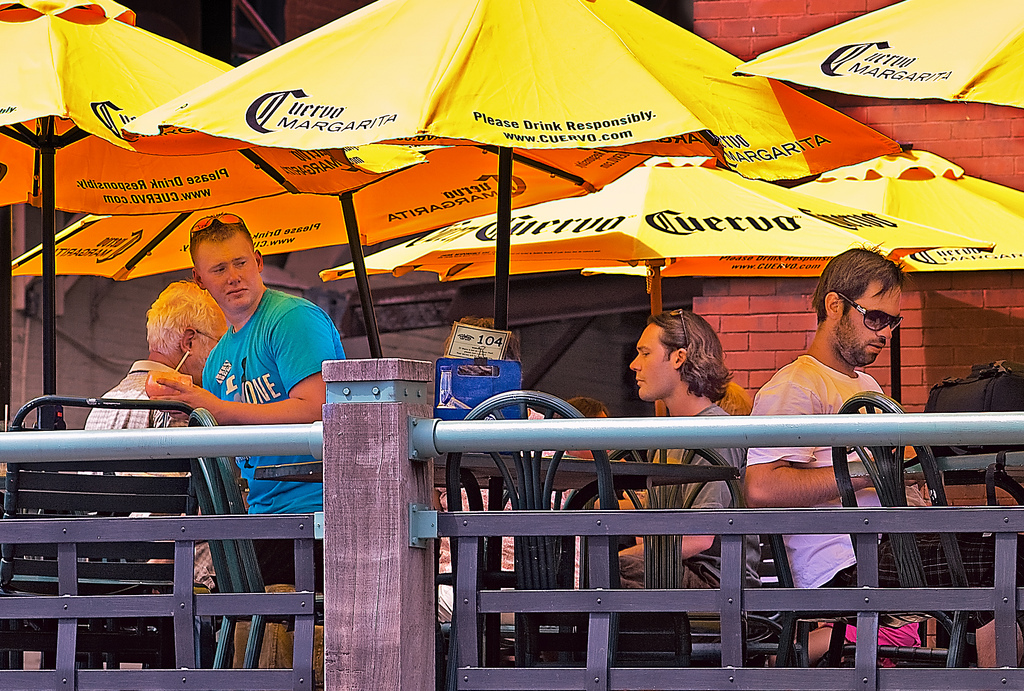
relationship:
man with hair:
[78, 290, 243, 576] [642, 305, 740, 385]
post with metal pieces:
[323, 344, 449, 625] [318, 344, 453, 424]